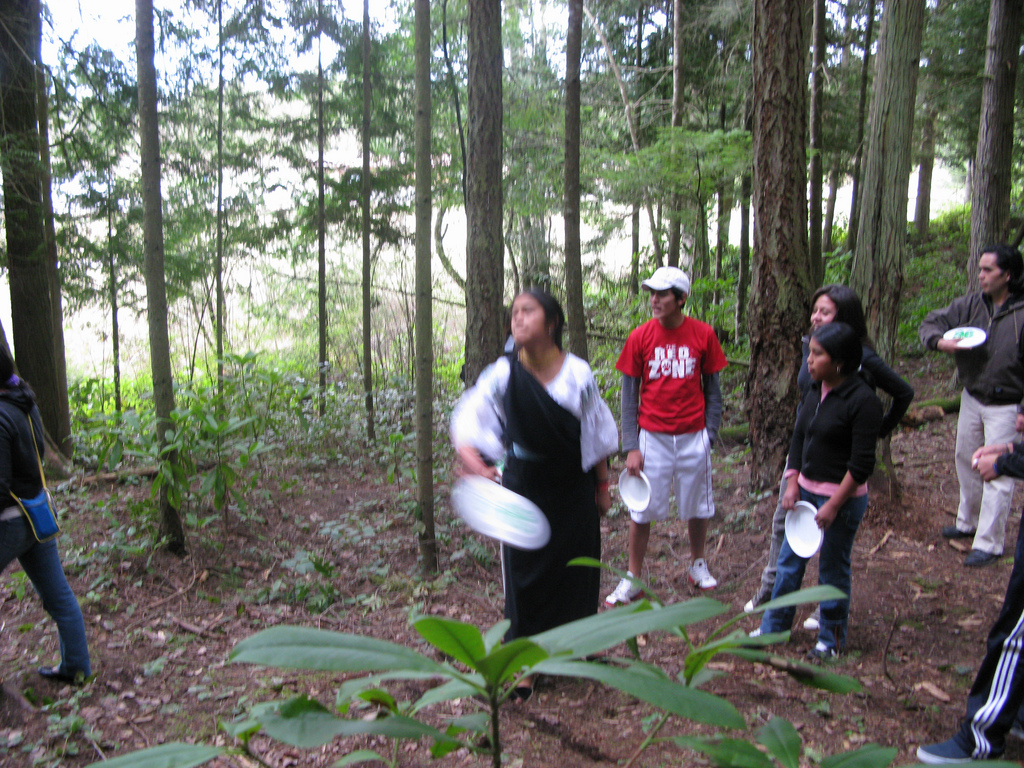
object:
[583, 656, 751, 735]
leaves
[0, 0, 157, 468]
tree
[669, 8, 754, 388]
tree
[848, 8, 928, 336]
tree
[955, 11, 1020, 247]
tree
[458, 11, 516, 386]
tree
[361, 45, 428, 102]
leaves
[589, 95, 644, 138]
leaves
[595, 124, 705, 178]
green leaves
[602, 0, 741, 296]
tree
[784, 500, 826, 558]
frisbee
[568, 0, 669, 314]
tree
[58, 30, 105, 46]
leaves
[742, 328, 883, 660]
child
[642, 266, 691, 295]
cap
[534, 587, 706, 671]
plant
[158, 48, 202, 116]
green leaves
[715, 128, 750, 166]
leaf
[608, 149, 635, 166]
leaf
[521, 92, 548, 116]
leaf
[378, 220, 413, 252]
leaf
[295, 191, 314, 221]
leaf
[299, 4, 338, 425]
tree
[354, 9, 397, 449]
tree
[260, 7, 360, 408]
tree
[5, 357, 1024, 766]
ground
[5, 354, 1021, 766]
dirt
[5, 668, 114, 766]
branches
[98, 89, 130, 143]
green leaves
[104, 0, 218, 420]
tree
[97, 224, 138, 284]
green leaves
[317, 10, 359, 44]
green leaves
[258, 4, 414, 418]
tree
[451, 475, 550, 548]
frisbee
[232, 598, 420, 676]
leaves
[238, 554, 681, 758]
plant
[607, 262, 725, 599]
man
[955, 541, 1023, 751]
leg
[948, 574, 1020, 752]
pants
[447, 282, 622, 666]
lady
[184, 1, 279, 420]
tree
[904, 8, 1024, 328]
tree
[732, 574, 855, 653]
leaves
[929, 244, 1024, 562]
man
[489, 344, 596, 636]
dress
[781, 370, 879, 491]
sweater